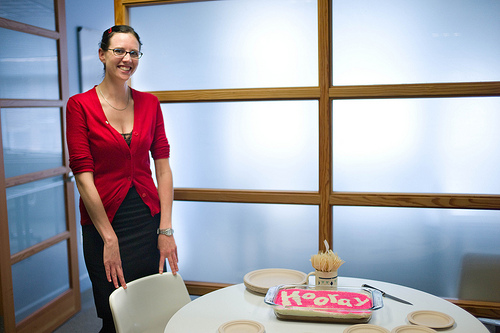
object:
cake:
[274, 286, 375, 323]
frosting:
[274, 287, 373, 313]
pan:
[264, 283, 384, 324]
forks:
[308, 238, 346, 271]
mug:
[306, 269, 342, 288]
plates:
[244, 267, 308, 293]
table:
[164, 274, 495, 332]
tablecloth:
[160, 276, 493, 332]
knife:
[361, 280, 416, 307]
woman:
[66, 24, 181, 332]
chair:
[106, 271, 196, 331]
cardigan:
[65, 84, 172, 228]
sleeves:
[65, 101, 96, 174]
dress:
[83, 184, 173, 320]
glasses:
[102, 46, 144, 60]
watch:
[155, 226, 177, 236]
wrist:
[156, 223, 177, 240]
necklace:
[97, 82, 135, 112]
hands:
[102, 233, 127, 289]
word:
[278, 288, 370, 310]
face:
[102, 32, 141, 81]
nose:
[122, 52, 135, 65]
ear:
[96, 47, 109, 64]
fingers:
[156, 249, 166, 276]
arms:
[61, 100, 117, 237]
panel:
[4, 0, 499, 332]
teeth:
[117, 64, 133, 72]